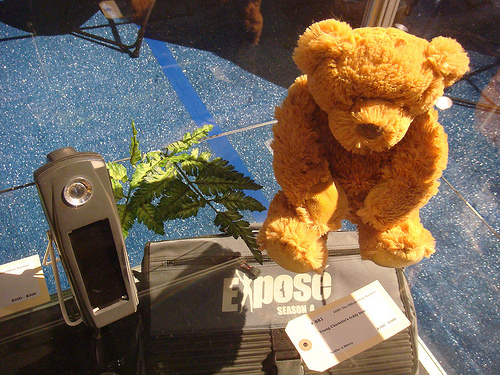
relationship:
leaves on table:
[101, 118, 265, 265] [1, 118, 499, 374]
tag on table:
[284, 280, 411, 372] [1, 118, 499, 374]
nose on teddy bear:
[354, 122, 382, 137] [257, 17, 468, 266]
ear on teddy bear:
[429, 35, 469, 80] [257, 17, 468, 266]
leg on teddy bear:
[358, 203, 437, 268] [257, 17, 468, 266]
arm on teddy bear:
[273, 74, 349, 227] [257, 17, 468, 266]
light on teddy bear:
[429, 121, 451, 201] [257, 17, 468, 266]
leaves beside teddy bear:
[101, 118, 265, 265] [257, 17, 468, 266]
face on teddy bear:
[293, 16, 470, 153] [257, 17, 468, 266]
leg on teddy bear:
[257, 190, 328, 271] [257, 17, 468, 266]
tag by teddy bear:
[284, 280, 411, 372] [257, 17, 468, 266]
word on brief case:
[222, 271, 333, 312] [139, 228, 419, 374]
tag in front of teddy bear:
[284, 280, 411, 372] [257, 17, 468, 266]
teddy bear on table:
[257, 17, 468, 266] [1, 118, 499, 374]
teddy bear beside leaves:
[257, 17, 468, 266] [101, 118, 265, 265]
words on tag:
[318, 309, 366, 332] [284, 280, 411, 372]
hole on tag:
[303, 342, 308, 346] [284, 280, 411, 372]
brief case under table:
[139, 228, 419, 374] [1, 118, 499, 374]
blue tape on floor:
[137, 21, 225, 136] [2, 31, 237, 156]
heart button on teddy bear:
[394, 37, 406, 50] [257, 17, 468, 266]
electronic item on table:
[35, 146, 140, 336] [1, 118, 499, 374]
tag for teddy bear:
[284, 280, 411, 372] [257, 17, 468, 266]